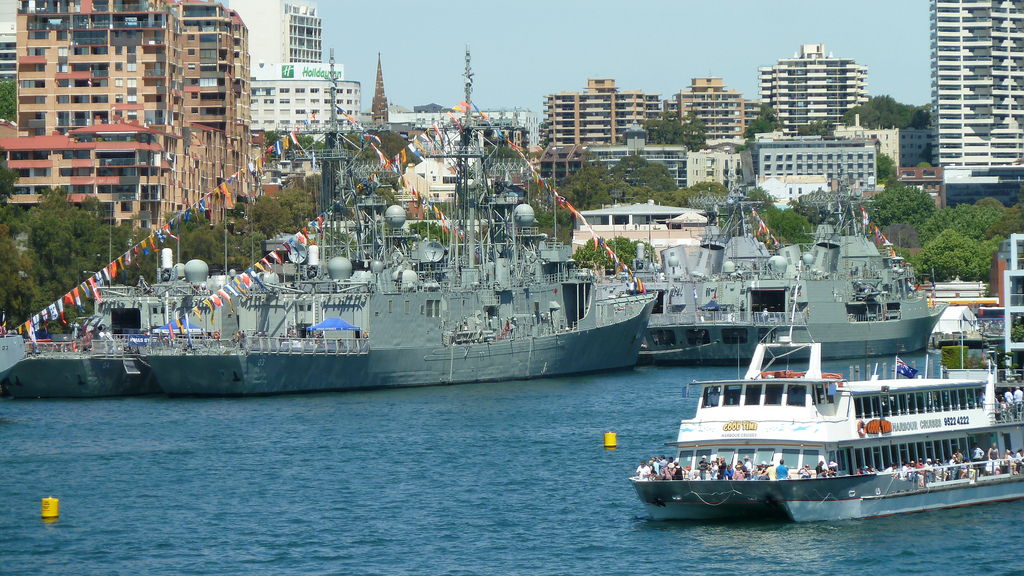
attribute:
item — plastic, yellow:
[40, 494, 58, 516]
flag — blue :
[894, 360, 916, 380]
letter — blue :
[946, 416, 972, 427]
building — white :
[929, 4, 1018, 206]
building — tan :
[1, 3, 256, 237]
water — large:
[3, 336, 1004, 561]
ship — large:
[642, 203, 938, 364]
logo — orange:
[856, 402, 900, 452]